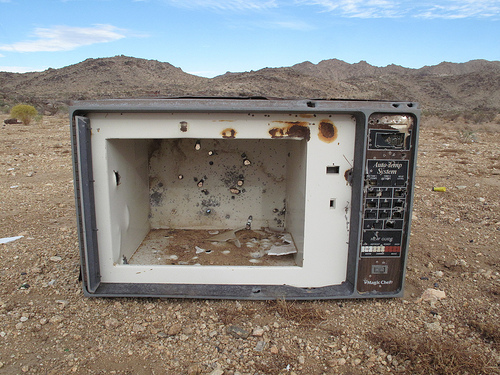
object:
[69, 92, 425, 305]
microwave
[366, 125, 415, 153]
dial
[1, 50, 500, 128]
hill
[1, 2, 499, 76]
sky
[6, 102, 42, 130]
bush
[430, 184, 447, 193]
object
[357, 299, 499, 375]
vegetation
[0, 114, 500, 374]
dirt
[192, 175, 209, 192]
bullet hole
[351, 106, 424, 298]
control panel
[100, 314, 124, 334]
rock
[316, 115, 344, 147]
area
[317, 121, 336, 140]
hole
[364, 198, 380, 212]
holes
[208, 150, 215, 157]
hole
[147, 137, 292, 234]
back wall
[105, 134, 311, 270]
interior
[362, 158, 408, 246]
keypad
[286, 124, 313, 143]
spot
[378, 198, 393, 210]
button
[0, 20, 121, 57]
cloud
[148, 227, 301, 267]
dirt